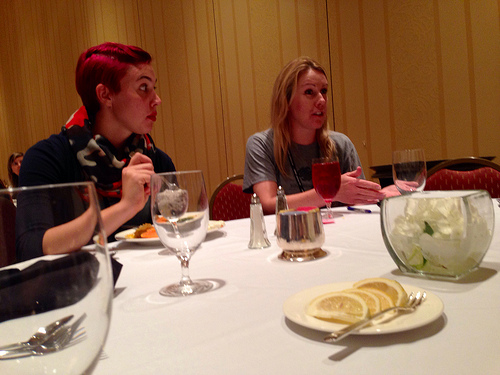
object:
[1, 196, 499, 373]
table cloth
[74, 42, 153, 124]
hair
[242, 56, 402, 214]
girl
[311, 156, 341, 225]
glass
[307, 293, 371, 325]
lemon slices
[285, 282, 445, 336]
plate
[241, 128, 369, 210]
shirt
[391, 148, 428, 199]
glass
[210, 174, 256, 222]
chairs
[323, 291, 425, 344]
forks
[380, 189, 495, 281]
bowl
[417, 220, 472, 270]
flowers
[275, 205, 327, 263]
container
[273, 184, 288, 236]
shakers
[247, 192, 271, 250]
salt shaker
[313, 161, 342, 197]
liquid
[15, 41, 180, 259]
woman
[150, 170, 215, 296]
glass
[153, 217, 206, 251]
water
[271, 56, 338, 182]
hair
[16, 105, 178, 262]
hoodie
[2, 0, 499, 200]
wall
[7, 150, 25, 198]
women